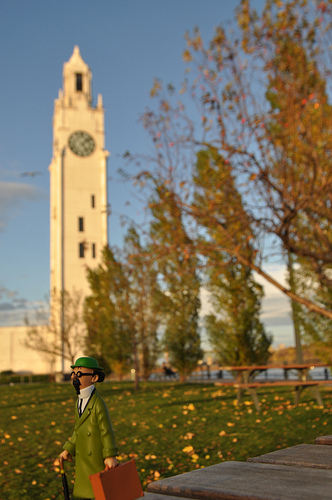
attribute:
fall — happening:
[6, 52, 316, 469]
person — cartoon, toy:
[39, 359, 148, 497]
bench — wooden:
[203, 360, 328, 407]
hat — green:
[45, 349, 107, 374]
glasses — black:
[67, 370, 96, 378]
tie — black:
[80, 399, 89, 412]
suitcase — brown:
[90, 453, 145, 497]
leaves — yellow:
[139, 425, 235, 483]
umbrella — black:
[54, 454, 74, 498]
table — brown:
[215, 368, 318, 408]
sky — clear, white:
[0, 6, 276, 307]